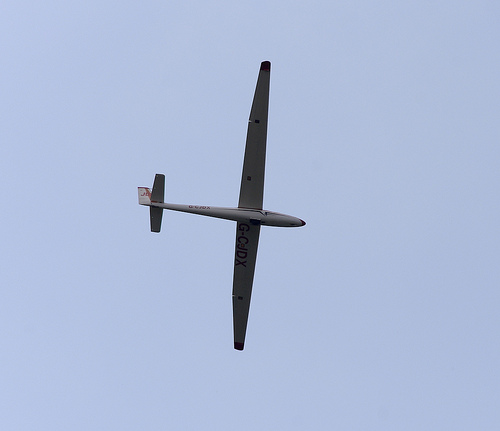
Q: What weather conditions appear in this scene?
A: It is clear.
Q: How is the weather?
A: It is clear.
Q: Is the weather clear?
A: Yes, it is clear.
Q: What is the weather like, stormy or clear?
A: It is clear.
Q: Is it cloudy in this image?
A: No, it is clear.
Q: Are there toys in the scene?
A: No, there are no toys.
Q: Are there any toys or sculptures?
A: No, there are no toys or sculptures.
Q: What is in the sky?
A: The clouds are in the sky.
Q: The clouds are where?
A: The clouds are in the sky.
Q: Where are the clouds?
A: The clouds are in the sky.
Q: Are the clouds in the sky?
A: Yes, the clouds are in the sky.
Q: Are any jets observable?
A: No, there are no jets.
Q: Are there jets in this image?
A: No, there are no jets.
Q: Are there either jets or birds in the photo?
A: No, there are no jets or birds.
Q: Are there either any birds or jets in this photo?
A: No, there are no jets or birds.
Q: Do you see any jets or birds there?
A: No, there are no jets or birds.